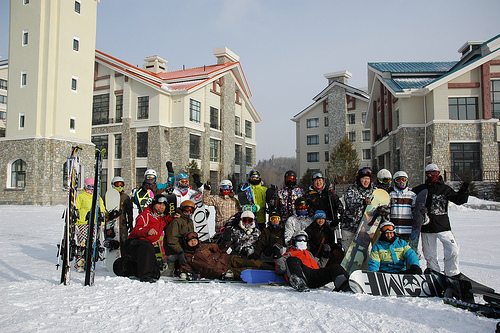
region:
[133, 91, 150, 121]
The window is rectangular.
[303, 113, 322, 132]
The window is rectangular.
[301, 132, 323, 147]
The window is rectangular.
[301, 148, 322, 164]
The window is rectangular.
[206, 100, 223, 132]
The window is rectangular.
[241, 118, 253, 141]
The window is rectangular.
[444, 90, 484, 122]
The window is rectangular.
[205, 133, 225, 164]
The window is rectangular.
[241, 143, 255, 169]
The window is rectangular.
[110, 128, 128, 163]
The window is rectangular.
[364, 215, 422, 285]
person in a green and blue coat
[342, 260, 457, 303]
white snowboard with black writing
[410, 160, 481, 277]
person wearing white pants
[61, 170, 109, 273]
person wearing a yellow coat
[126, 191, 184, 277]
person wearing a red coat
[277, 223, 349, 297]
person wearing an orange coat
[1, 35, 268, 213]
large beige and stone building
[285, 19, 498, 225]
building with a blue roof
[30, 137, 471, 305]
group of people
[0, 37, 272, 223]
building with a red roof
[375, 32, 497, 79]
The blue roof of the building.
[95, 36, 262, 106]
The red roof of the building.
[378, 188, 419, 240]
The guy wearing the striped shirt.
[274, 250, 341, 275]
The guy wearing the orange and gray jacket.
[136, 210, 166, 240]
The guy wearing the red jacket.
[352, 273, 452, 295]
The black and white snowboard in front of the guy on the right.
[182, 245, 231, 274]
The guy wearing the brown jacket.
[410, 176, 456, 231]
The guy on the right wearing a black jacket.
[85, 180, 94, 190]
The pink helmet on the person's head on the left.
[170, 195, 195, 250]
The guy wearing the brown helmet.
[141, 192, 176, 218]
the head of a man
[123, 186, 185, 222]
a man wearing a hat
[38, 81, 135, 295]
skis in the snow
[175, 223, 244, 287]
a man with a brown coat on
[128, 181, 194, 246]
a man with a red coat on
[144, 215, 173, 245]
the hand of a man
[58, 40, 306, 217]
a building in the background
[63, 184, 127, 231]
a person with a yellow jacket on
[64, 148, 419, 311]
a group of people in the snow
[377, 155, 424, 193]
a man wearing goggles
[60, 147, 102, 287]
A pair of skies.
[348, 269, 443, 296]
A snowboard.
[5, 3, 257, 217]
A skie resort.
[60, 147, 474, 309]
A group picture at a skie resort.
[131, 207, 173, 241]
A red snow suit.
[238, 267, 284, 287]
A blue snowboard.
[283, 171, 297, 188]
Red skie goggles.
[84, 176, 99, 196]
A pink winter hat.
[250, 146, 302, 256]
A tree in the background of a picture.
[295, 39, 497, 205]
A ski lodge.